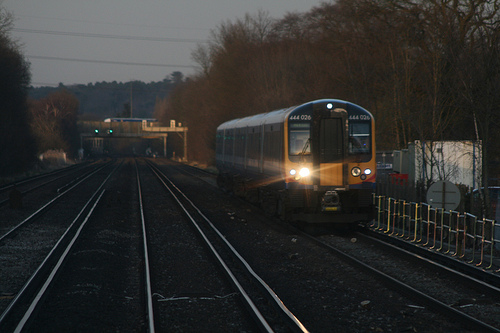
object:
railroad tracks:
[161, 155, 500, 332]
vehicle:
[102, 117, 157, 123]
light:
[295, 165, 312, 177]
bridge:
[75, 118, 189, 158]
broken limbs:
[153, 288, 243, 306]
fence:
[367, 193, 500, 275]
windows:
[348, 136, 371, 154]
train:
[215, 99, 376, 228]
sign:
[426, 180, 460, 214]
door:
[316, 120, 343, 189]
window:
[264, 132, 282, 158]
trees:
[155, 0, 498, 187]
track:
[0, 156, 123, 332]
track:
[134, 159, 310, 332]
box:
[406, 140, 483, 189]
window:
[286, 133, 308, 154]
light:
[289, 167, 299, 176]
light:
[351, 167, 364, 174]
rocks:
[357, 297, 373, 307]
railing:
[480, 218, 495, 223]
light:
[106, 127, 114, 135]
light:
[92, 127, 99, 133]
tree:
[0, 6, 34, 176]